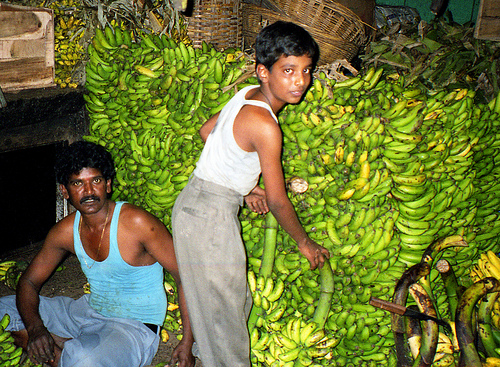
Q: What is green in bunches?
A: Bananas.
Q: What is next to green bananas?
A: A Boy.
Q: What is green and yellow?
A: Bananas.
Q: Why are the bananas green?
A: Unripened.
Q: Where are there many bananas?
A: Beside boy.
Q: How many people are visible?
A: Two.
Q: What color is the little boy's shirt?
A: White.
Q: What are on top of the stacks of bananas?
A: Baskets.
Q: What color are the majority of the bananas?
A: Green.